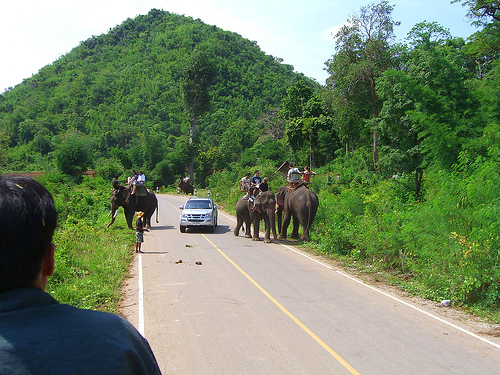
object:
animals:
[107, 186, 320, 244]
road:
[113, 193, 500, 375]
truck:
[179, 197, 217, 233]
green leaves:
[404, 80, 433, 120]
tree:
[364, 42, 500, 229]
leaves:
[89, 72, 118, 102]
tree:
[90, 69, 121, 104]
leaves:
[68, 138, 85, 166]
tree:
[55, 135, 94, 179]